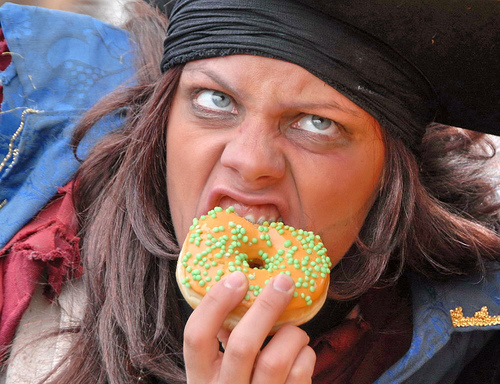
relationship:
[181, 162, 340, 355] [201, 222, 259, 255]
donut has sprinkles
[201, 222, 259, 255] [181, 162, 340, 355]
sprinkles on donut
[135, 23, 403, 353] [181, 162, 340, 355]
woman hold donut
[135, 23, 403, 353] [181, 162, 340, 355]
woman eating donut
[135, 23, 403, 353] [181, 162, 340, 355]
woman holding donut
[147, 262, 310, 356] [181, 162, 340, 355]
hand holding donut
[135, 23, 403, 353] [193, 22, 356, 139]
woman looking up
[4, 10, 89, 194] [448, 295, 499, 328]
cloth has design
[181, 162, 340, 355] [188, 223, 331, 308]
donut has icing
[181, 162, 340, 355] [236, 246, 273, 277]
donut has hole